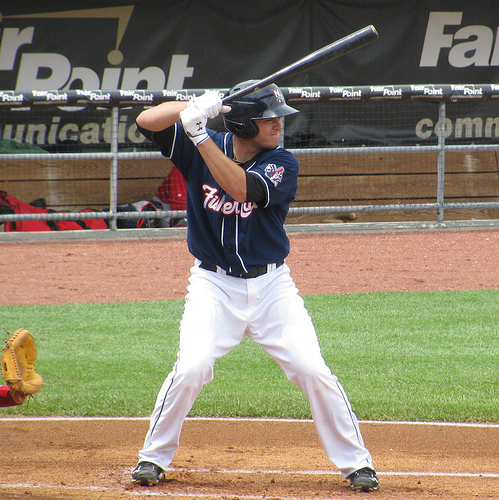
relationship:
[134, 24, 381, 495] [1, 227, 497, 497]
man on field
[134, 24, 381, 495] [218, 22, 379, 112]
man has bat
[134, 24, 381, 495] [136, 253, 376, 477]
man wearing pants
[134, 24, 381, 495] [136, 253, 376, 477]
man has pants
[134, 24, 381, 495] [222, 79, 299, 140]
man wearing helmet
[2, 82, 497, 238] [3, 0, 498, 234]
fence in front of dugout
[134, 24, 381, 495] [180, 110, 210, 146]
man wearing gloves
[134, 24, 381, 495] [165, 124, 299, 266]
man wearing jersey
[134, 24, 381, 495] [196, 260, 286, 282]
man wearing belt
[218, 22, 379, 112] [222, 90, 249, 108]
bat has handle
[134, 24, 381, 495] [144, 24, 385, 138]
man playing baseball